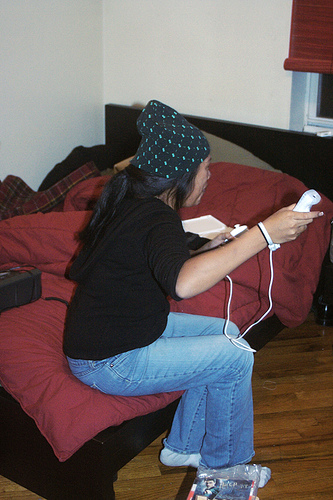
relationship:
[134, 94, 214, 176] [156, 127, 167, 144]
hat has dots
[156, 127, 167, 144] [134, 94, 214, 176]
dots cover hat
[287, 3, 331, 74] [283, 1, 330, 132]
blinds are in front of window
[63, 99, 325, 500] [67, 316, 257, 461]
woman wearing jeans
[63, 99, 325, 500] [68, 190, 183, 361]
woman wearing a shirt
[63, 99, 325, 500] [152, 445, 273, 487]
woman wearing socks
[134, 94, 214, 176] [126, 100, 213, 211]
hat on head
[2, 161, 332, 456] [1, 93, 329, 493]
blanket on top of bed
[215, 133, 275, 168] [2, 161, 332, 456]
pillow under blanket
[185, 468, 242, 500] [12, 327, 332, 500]
book on floors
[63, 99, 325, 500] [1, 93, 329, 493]
woman sitting on top of bed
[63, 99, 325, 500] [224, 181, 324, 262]
woman holding wiimote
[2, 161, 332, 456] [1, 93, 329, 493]
blanket covers bed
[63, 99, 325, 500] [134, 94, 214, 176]
woman wearing a hat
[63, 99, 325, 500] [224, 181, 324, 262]
woman holding up a wiimote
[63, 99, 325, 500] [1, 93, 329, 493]
woman sitting on bed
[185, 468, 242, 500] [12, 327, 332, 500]
books are lying on top of floors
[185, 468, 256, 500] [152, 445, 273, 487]
book are sitting right of socks